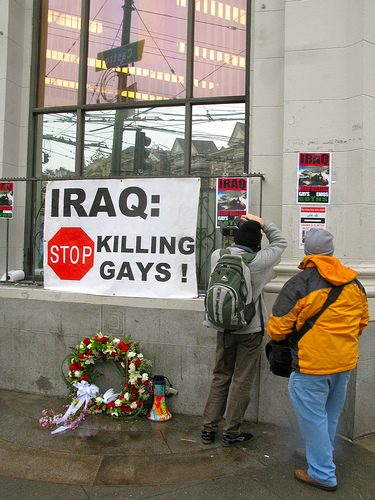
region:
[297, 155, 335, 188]
a paper on a wall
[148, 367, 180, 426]
a colorful microphone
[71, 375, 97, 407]
a ribbon on a wreath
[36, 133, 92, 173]
a window on a building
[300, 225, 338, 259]
a person wearing a hat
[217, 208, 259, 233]
a person with a camera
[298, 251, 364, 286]
a jacket with a hood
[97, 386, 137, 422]
flowers on a wreath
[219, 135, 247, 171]
refelection of a house in the window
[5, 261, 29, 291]
paper towels near the windows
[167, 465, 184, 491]
aprt of a floor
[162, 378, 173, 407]
par of a wall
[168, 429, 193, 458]
part of a loine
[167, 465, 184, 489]
part of a floor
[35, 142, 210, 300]
a bit white board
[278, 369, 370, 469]
pant o f theperson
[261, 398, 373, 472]
a man wearing pants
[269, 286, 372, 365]
a man wearing jacket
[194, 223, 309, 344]
a man wearing shirt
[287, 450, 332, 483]
a man wearing shoes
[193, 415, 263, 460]
a man wearing boot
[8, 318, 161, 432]
a garland next to man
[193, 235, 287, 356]
bag on the back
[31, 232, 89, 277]
a symbol in board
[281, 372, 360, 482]
the pants are blue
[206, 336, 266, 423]
the pants are brown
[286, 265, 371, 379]
the jacket is orange and black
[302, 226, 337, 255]
the marvin is grey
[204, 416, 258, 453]
the shoes are black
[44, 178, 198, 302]
sign says iraq lkilling gays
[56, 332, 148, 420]
the flowers are red and white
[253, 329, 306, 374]
the bag is black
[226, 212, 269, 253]
the marvin is black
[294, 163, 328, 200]
photos are on the wall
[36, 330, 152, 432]
a wreath of flowers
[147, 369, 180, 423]
a multicolored megaphone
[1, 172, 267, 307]
some metal railing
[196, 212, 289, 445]
a person in a grey shirt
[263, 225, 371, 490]
a person in an orange jacket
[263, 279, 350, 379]
a black bag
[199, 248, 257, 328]
a grey and green backpack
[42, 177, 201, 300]
a large white sign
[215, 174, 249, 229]
A hanging sign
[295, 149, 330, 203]
a sign on the wall